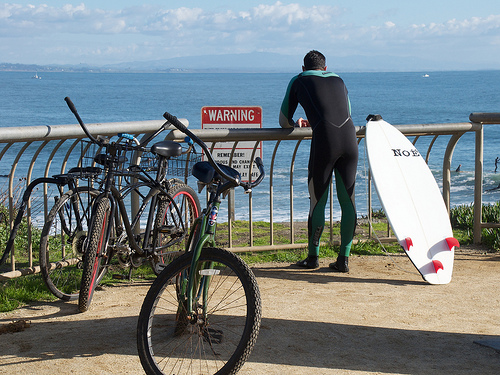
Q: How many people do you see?
A: 1.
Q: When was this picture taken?
A: During daylight.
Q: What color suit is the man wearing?
A: Black.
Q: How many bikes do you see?
A: 3.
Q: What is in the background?
A: Water.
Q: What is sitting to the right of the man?
A: A Surfboard.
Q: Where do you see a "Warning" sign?
A: Behind the fence.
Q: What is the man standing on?
A: Dirt.